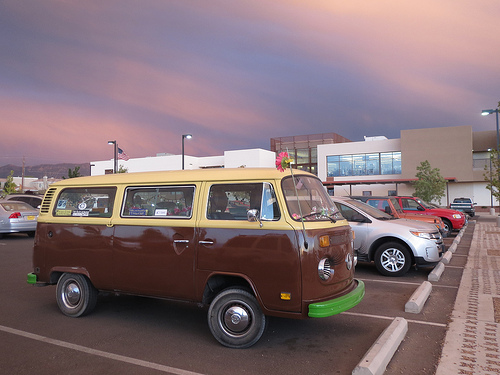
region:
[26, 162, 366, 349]
Brown VW van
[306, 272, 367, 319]
green bumper on VW van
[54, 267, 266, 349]
wheels on one side of VW van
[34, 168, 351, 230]
top of VW van is light brown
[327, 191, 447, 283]
silver car parked next to VW van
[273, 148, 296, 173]
flower mounted on VW van's antenna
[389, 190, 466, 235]
red car parked in parking lot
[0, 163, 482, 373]
cars parked in a parking lot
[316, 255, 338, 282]
headlight of VW van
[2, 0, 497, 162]
sky is dark blue with streaks of clouds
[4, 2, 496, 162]
clouds in blue sky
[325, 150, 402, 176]
lights on in building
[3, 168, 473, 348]
vehicles parked in lot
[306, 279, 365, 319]
green bumper on bus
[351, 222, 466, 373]
cement blocks on asphalt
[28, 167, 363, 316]
brown and tan bus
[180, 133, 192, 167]
light on top of pole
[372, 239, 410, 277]
wheel on parked vehicle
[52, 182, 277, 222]
windows on side of van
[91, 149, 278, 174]
top of white building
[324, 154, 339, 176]
glass window on building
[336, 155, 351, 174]
glass window on building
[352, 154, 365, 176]
glass window on building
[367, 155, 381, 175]
glass window on building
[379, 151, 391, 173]
glass window on building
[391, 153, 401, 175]
glass window on building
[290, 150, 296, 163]
glass window on building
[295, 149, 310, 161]
glass window on building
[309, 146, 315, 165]
glass window on building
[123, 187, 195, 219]
glass window on bus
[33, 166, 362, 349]
a brown and tan Volkswagon van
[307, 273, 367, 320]
a green bumper on a van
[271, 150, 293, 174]
a flower on an antenna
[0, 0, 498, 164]
a blue and pinky white streaked sky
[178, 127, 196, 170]
a lit street lamp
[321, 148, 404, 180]
a large glass windowed wall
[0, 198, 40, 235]
a silver car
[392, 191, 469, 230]
a red vehicle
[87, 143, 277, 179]
a white building behind a van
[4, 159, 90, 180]
a mountain in the distance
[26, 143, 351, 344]
A old van parked in the parking lot.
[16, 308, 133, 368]
White line in the parking lot.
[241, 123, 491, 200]
A building in the parking lot.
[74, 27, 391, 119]
The sky is dark and overcast.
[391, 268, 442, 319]
White parking blocks in the lot.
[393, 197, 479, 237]
A red car is parked.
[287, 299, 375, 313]
The van has a green bumper.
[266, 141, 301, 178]
A flower on the antenna of the van.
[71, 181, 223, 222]
Windows of the van.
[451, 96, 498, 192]
Street light pole on sidewalk.